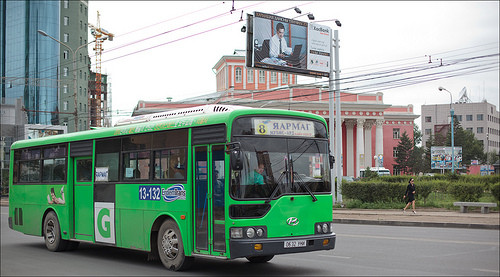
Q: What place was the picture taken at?
A: It was taken at the road.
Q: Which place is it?
A: It is a road.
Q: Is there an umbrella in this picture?
A: No, there are no umbrellas.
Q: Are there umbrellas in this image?
A: No, there are no umbrellas.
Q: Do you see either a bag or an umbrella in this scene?
A: No, there are no umbrellas or bags.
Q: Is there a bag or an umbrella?
A: No, there are no umbrellas or bags.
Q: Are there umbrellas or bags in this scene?
A: No, there are no umbrellas or bags.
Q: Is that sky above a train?
A: No, the sky is above the bus.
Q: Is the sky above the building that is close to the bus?
A: Yes, the sky is above the building.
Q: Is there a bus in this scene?
A: Yes, there is a bus.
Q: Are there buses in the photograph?
A: Yes, there is a bus.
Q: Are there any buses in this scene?
A: Yes, there is a bus.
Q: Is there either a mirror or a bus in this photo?
A: Yes, there is a bus.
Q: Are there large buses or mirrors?
A: Yes, there is a large bus.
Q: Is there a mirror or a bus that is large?
A: Yes, the bus is large.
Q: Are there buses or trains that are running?
A: Yes, the bus is running.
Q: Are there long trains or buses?
A: Yes, there is a long bus.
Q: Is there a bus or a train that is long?
A: Yes, the bus is long.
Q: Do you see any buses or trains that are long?
A: Yes, the bus is long.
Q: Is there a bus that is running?
A: Yes, there is a bus that is running.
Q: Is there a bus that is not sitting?
A: Yes, there is a bus that is running.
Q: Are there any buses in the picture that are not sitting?
A: Yes, there is a bus that is running.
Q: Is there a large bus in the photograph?
A: Yes, there is a large bus.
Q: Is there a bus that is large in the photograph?
A: Yes, there is a large bus.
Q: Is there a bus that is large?
A: Yes, there is a bus that is large.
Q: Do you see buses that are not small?
A: Yes, there is a large bus.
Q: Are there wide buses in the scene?
A: Yes, there is a wide bus.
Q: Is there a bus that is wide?
A: Yes, there is a bus that is wide.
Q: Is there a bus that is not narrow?
A: Yes, there is a wide bus.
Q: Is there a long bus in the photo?
A: Yes, there is a long bus.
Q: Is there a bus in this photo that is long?
A: Yes, there is a bus that is long.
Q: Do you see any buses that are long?
A: Yes, there is a bus that is long.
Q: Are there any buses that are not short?
A: Yes, there is a long bus.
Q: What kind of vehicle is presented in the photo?
A: The vehicle is a bus.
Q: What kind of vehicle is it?
A: The vehicle is a bus.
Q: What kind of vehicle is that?
A: That is a bus.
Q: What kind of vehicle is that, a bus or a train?
A: That is a bus.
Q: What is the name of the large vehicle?
A: The vehicle is a bus.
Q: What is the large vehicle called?
A: The vehicle is a bus.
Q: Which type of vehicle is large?
A: The vehicle is a bus.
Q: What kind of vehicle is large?
A: The vehicle is a bus.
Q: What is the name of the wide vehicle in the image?
A: The vehicle is a bus.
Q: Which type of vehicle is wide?
A: The vehicle is a bus.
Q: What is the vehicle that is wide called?
A: The vehicle is a bus.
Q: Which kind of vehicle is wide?
A: The vehicle is a bus.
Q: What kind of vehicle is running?
A: The vehicle is a bus.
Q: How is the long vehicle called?
A: The vehicle is a bus.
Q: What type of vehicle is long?
A: The vehicle is a bus.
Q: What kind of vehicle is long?
A: The vehicle is a bus.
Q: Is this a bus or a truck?
A: This is a bus.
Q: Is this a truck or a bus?
A: This is a bus.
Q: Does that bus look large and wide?
A: Yes, the bus is large and wide.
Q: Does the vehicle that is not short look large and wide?
A: Yes, the bus is large and wide.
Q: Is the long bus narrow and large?
A: No, the bus is large but wide.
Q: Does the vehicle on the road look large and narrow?
A: No, the bus is large but wide.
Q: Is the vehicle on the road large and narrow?
A: No, the bus is large but wide.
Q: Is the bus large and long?
A: Yes, the bus is large and long.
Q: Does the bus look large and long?
A: Yes, the bus is large and long.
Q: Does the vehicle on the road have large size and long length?
A: Yes, the bus is large and long.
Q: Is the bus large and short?
A: No, the bus is large but long.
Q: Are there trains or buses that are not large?
A: No, there is a bus but it is large.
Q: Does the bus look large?
A: Yes, the bus is large.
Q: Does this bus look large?
A: Yes, the bus is large.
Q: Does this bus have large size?
A: Yes, the bus is large.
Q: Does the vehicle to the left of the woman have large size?
A: Yes, the bus is large.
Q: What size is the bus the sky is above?
A: The bus is large.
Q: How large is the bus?
A: The bus is large.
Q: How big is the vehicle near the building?
A: The bus is large.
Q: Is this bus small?
A: No, the bus is large.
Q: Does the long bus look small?
A: No, the bus is large.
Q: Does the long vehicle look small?
A: No, the bus is large.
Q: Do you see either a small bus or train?
A: No, there is a bus but it is large.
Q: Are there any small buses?
A: No, there is a bus but it is large.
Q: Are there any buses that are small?
A: No, there is a bus but it is large.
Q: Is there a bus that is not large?
A: No, there is a bus but it is large.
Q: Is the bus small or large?
A: The bus is large.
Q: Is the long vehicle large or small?
A: The bus is large.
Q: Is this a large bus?
A: Yes, this is a large bus.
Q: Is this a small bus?
A: No, this is a large bus.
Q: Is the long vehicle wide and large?
A: Yes, the bus is wide and large.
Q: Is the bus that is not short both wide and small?
A: No, the bus is wide but large.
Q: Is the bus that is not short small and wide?
A: No, the bus is wide but large.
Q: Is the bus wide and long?
A: Yes, the bus is wide and long.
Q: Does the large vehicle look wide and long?
A: Yes, the bus is wide and long.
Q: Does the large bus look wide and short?
A: No, the bus is wide but long.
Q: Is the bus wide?
A: Yes, the bus is wide.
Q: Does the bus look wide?
A: Yes, the bus is wide.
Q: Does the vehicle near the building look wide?
A: Yes, the bus is wide.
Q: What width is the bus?
A: The bus is wide.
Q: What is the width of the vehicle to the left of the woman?
A: The bus is wide.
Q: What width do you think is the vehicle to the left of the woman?
A: The bus is wide.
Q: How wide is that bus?
A: The bus is wide.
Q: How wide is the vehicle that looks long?
A: The bus is wide.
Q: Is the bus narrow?
A: No, the bus is wide.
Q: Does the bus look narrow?
A: No, the bus is wide.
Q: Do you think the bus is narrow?
A: No, the bus is wide.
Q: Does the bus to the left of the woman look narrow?
A: No, the bus is wide.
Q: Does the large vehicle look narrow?
A: No, the bus is wide.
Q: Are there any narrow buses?
A: No, there is a bus but it is wide.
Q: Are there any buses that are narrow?
A: No, there is a bus but it is wide.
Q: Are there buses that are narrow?
A: No, there is a bus but it is wide.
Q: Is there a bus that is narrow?
A: No, there is a bus but it is wide.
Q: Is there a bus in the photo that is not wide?
A: No, there is a bus but it is wide.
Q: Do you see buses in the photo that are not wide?
A: No, there is a bus but it is wide.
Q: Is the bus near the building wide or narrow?
A: The bus is wide.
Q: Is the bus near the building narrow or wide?
A: The bus is wide.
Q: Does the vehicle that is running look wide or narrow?
A: The bus is wide.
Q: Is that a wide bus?
A: Yes, that is a wide bus.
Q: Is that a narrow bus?
A: No, that is a wide bus.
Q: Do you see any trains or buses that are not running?
A: No, there is a bus but it is running.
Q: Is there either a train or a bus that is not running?
A: No, there is a bus but it is running.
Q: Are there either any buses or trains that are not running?
A: No, there is a bus but it is running.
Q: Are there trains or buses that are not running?
A: No, there is a bus but it is running.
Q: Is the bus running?
A: Yes, the bus is running.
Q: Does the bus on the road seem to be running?
A: Yes, the bus is running.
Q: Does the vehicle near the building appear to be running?
A: Yes, the bus is running.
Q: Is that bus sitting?
A: No, the bus is running.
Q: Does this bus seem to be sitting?
A: No, the bus is running.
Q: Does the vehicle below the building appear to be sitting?
A: No, the bus is running.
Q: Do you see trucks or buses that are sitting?
A: No, there is a bus but it is running.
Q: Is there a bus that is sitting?
A: No, there is a bus but it is running.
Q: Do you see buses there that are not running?
A: No, there is a bus but it is running.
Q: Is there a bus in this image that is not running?
A: No, there is a bus but it is running.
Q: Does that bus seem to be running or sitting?
A: The bus is running.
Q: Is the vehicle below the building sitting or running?
A: The bus is running.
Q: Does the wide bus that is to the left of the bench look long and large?
A: Yes, the bus is long and large.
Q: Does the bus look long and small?
A: No, the bus is long but large.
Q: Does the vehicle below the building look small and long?
A: No, the bus is long but large.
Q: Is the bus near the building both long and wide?
A: Yes, the bus is long and wide.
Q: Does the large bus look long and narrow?
A: No, the bus is long but wide.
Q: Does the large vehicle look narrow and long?
A: No, the bus is long but wide.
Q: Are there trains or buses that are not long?
A: No, there is a bus but it is long.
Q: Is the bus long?
A: Yes, the bus is long.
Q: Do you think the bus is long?
A: Yes, the bus is long.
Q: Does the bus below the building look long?
A: Yes, the bus is long.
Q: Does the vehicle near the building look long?
A: Yes, the bus is long.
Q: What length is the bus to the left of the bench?
A: The bus is long.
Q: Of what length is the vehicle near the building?
A: The bus is long.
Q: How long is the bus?
A: The bus is long.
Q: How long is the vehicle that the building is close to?
A: The bus is long.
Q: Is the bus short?
A: No, the bus is long.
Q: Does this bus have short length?
A: No, the bus is long.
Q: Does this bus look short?
A: No, the bus is long.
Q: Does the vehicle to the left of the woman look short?
A: No, the bus is long.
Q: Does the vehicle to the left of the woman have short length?
A: No, the bus is long.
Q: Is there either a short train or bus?
A: No, there is a bus but it is long.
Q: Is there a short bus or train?
A: No, there is a bus but it is long.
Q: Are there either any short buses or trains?
A: No, there is a bus but it is long.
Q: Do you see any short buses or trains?
A: No, there is a bus but it is long.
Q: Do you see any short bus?
A: No, there is a bus but it is long.